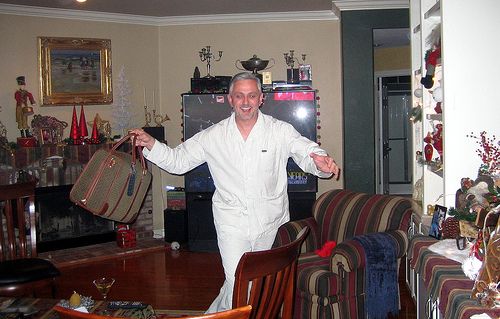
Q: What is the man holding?
A: A suitcase.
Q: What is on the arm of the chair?
A: Blue blanket.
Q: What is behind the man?
A: A tv.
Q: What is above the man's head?
A: A trophy.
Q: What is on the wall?
A: A painting in a gold frame.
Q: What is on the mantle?
A: Christmas decorations.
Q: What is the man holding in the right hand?
A: Traveling bag.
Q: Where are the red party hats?
A: On top of the fireplace.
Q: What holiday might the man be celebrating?
A: Christmas.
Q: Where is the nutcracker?
A: Left side of fireplace.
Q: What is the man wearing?
A: White robe.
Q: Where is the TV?
A: Behind the man.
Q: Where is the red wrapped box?
A: Bottom right of fireplace.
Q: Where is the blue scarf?
A: On the red and green arm rest.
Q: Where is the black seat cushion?
A: On the left chair.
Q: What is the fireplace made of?
A: Brick.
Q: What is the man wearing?
A: Robe.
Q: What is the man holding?
A: Suitcase.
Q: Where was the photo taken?
A: Living room.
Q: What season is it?
A: Christmas.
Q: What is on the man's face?
A: Smile.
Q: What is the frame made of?
A: Gold.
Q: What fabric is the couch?
A: Striped.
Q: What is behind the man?
A: Tv.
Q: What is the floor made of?
A: Wood.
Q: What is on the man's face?
A: Beard.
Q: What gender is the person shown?
A: Male.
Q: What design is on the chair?
A: Stripes.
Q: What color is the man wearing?
A: White.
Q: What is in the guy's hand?
A: A bag.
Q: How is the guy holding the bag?
A: With one hand.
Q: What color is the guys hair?
A: Gray.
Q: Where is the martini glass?
A: A coffee table.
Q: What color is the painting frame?
A: Gold.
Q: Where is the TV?
A: Behind the man.